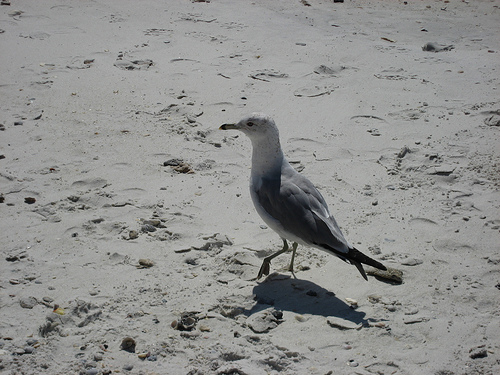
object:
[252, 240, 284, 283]
feet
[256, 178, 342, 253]
wing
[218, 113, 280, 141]
head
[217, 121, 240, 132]
beak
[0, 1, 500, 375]
depressions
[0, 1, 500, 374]
sand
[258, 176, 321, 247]
feathers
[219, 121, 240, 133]
tip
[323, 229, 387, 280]
tail feather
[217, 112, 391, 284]
bird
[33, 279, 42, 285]
rocks